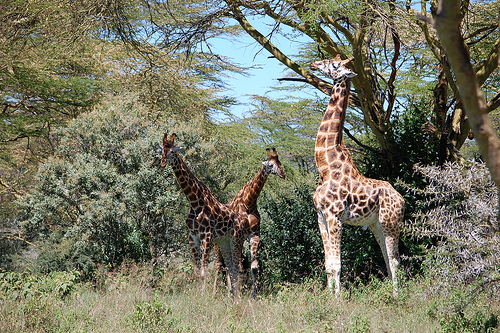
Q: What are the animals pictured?
A: Giraffes.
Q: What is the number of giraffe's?
A: Three.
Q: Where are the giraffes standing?
A: Dry grass.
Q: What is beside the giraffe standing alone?
A: A tree.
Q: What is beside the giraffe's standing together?
A: A bush.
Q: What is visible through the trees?
A: Blue sky.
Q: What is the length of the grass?
A: Very long.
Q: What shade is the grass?
A: Green and brown.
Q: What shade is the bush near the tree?
A: Purple.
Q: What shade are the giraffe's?
A: Brown and white.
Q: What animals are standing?
A: Giraffes.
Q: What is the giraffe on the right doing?
A: Eating leaves.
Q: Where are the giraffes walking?
A: Through the grass.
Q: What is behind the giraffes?
A: Trees.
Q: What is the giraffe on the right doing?
A: Eating tree leaves.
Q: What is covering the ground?
A: Long grass.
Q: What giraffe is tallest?
A: The one on the right.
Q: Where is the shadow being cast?
A: On the giraffes in the middle.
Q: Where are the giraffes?
A: Near the trees.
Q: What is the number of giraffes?
A: 3.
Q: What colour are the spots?
A: Brown.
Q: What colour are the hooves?
A: Brown.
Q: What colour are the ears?
A: Brown.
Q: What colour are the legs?
A: Brown.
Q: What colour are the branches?
A: Brown.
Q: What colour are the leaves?
A: Green.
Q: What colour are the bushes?
A: Green.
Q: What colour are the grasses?
A: Green.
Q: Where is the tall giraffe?
A: Under the trees.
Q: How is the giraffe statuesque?
A: Standing straight with neck stretched out.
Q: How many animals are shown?
A: Three.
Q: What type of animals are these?
A: Giraffes.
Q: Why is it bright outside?
A: It's daytime.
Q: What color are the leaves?
A: Green.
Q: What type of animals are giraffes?
A: Mammals.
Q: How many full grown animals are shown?
A: One.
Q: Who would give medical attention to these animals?
A: Veterinarian.